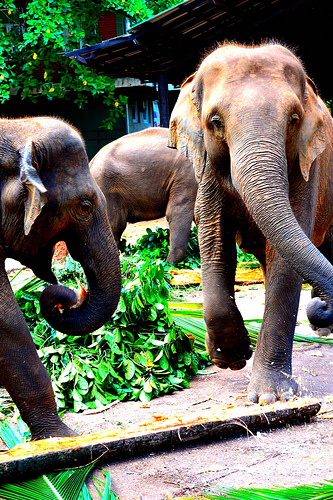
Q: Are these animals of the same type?
A: Yes, all the animals are elephants.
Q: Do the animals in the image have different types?
A: No, all the animals are elephants.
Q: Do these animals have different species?
A: No, all the animals are elephants.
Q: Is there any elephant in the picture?
A: Yes, there is an elephant.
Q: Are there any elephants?
A: Yes, there is an elephant.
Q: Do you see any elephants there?
A: Yes, there is an elephant.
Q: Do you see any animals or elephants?
A: Yes, there is an elephant.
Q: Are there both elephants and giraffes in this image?
A: No, there is an elephant but no giraffes.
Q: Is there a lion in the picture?
A: No, there are no lions.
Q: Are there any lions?
A: No, there are no lions.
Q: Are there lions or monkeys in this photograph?
A: No, there are no lions or monkeys.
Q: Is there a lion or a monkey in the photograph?
A: No, there are no lions or monkeys.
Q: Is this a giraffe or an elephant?
A: This is an elephant.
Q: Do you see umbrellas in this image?
A: No, there are no umbrellas.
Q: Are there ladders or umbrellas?
A: No, there are no umbrellas or ladders.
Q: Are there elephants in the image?
A: Yes, there is an elephant.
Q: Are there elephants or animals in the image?
A: Yes, there is an elephant.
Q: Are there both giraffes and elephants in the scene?
A: No, there is an elephant but no giraffes.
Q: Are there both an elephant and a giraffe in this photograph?
A: No, there is an elephant but no giraffes.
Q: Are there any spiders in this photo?
A: No, there are no spiders.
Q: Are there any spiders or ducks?
A: No, there are no spiders or ducks.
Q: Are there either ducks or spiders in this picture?
A: No, there are no spiders or ducks.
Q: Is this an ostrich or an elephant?
A: This is an elephant.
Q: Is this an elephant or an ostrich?
A: This is an elephant.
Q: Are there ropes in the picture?
A: No, there are no ropes.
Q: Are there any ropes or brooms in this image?
A: No, there are no ropes or brooms.